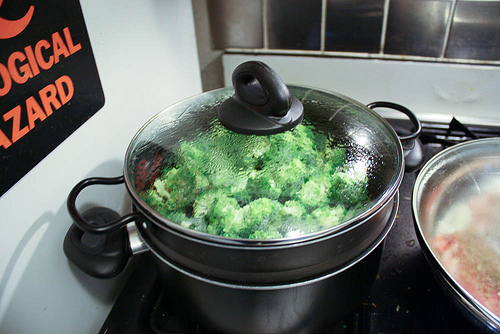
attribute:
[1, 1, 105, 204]
sign — black, orange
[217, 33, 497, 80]
trim — white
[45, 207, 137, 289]
handle — black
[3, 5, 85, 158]
print — orange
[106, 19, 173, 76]
wall — white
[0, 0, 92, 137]
letter — orange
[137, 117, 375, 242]
broccoli — steamed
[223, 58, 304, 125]
handle — black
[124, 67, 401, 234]
lid — glass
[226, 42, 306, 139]
handle — black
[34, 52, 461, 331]
pot — very large, steamer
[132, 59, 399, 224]
lid — black handle